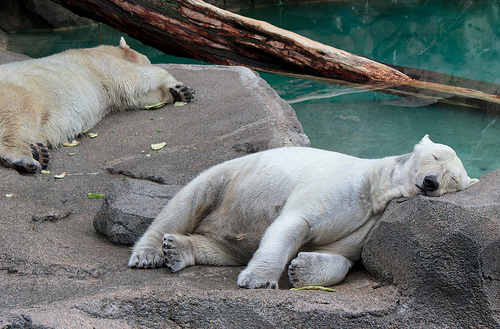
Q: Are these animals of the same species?
A: Yes, all the animals are bears.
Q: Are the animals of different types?
A: No, all the animals are bears.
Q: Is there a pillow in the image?
A: No, there are no pillows.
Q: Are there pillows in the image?
A: No, there are no pillows.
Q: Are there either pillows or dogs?
A: No, there are no pillows or dogs.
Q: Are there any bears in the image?
A: Yes, there is a bear.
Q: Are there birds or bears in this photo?
A: Yes, there is a bear.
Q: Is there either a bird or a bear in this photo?
A: Yes, there is a bear.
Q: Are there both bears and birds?
A: No, there is a bear but no birds.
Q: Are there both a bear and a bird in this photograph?
A: No, there is a bear but no birds.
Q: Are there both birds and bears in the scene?
A: No, there is a bear but no birds.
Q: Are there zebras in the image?
A: No, there are no zebras.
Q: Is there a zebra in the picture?
A: No, there are no zebras.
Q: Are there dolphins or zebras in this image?
A: No, there are no zebras or dolphins.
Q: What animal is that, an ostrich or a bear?
A: That is a bear.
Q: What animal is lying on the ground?
A: The animal is a bear.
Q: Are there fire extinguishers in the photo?
A: No, there are no fire extinguishers.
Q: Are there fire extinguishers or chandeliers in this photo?
A: No, there are no fire extinguishers or chandeliers.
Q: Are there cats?
A: No, there are no cats.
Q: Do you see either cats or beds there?
A: No, there are no cats or beds.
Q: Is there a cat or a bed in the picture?
A: No, there are no cats or beds.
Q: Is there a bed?
A: No, there are no beds.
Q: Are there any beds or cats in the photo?
A: No, there are no beds or cats.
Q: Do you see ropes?
A: No, there are no ropes.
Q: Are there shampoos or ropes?
A: No, there are no ropes or shampoos.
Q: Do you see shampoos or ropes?
A: No, there are no ropes or shampoos.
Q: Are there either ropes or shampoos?
A: No, there are no ropes or shampoos.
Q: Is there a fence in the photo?
A: No, there are no fences.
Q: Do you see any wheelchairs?
A: No, there are no wheelchairs.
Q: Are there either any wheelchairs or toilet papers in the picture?
A: No, there are no wheelchairs or toilet papers.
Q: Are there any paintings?
A: No, there are no paintings.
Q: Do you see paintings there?
A: No, there are no paintings.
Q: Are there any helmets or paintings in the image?
A: No, there are no paintings or helmets.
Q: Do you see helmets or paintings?
A: No, there are no paintings or helmets.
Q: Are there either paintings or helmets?
A: No, there are no paintings or helmets.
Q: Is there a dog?
A: No, there are no dogs.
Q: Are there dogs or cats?
A: No, there are no dogs or cats.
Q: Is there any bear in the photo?
A: Yes, there is a bear.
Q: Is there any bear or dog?
A: Yes, there is a bear.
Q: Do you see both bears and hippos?
A: No, there is a bear but no hippos.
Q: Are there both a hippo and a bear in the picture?
A: No, there is a bear but no hippos.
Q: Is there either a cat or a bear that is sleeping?
A: Yes, the bear is sleeping.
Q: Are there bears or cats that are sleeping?
A: Yes, the bear is sleeping.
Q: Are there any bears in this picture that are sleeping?
A: Yes, there is a bear that is sleeping.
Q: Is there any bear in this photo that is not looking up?
A: Yes, there is a bear that is sleeping.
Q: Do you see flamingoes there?
A: No, there are no flamingoes.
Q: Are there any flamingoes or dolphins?
A: No, there are no flamingoes or dolphins.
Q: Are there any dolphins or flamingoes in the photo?
A: No, there are no flamingoes or dolphins.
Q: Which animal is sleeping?
A: The animal is a bear.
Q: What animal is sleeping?
A: The animal is a bear.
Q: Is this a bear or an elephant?
A: This is a bear.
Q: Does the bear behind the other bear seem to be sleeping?
A: Yes, the bear is sleeping.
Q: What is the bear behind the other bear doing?
A: The bear is sleeping.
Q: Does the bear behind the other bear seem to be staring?
A: No, the bear is sleeping.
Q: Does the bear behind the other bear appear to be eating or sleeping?
A: The bear is sleeping.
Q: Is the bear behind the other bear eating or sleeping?
A: The bear is sleeping.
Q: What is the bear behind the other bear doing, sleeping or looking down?
A: The bear is sleeping.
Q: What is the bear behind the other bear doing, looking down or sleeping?
A: The bear is sleeping.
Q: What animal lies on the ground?
A: The animal is a bear.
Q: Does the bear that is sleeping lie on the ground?
A: Yes, the bear lies on the ground.